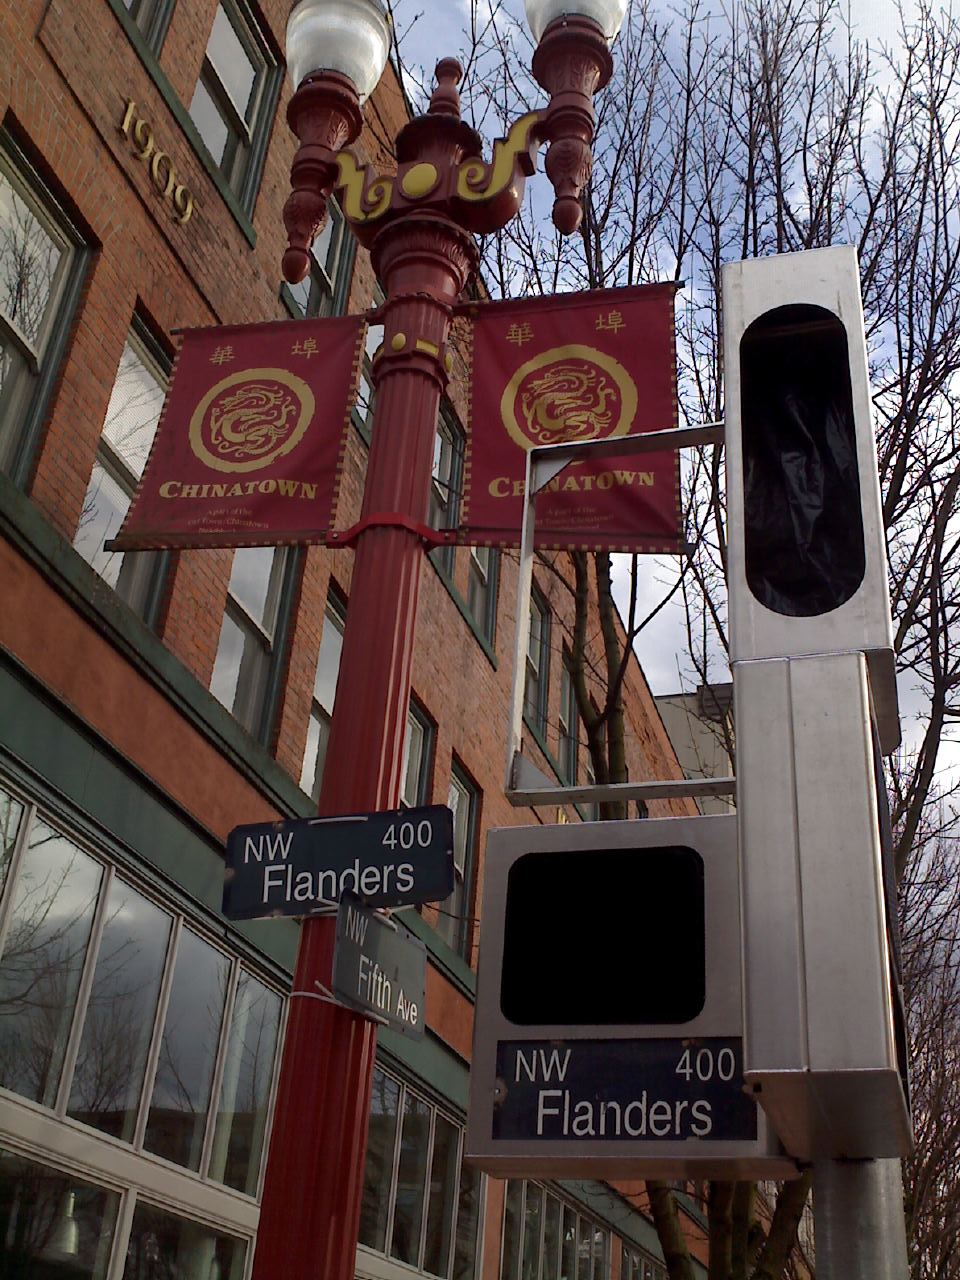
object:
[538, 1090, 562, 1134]
letter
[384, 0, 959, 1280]
tree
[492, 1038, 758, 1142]
sign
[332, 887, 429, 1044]
sign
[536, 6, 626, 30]
light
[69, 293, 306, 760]
window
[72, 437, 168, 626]
window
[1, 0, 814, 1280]
building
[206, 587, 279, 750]
window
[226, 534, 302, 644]
window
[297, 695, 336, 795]
window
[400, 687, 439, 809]
window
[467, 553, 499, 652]
window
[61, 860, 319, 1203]
window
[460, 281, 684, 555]
banner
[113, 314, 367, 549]
banner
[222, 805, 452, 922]
sign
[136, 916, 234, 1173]
window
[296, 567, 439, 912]
window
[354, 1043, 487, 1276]
window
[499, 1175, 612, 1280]
window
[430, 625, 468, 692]
bricks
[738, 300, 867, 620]
lamp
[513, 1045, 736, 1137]
words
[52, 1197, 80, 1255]
bell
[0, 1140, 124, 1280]
window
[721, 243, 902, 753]
plastic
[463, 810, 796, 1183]
plastic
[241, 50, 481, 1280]
lamppost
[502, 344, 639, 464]
logo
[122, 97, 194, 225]
number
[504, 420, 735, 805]
frame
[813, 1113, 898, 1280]
pole